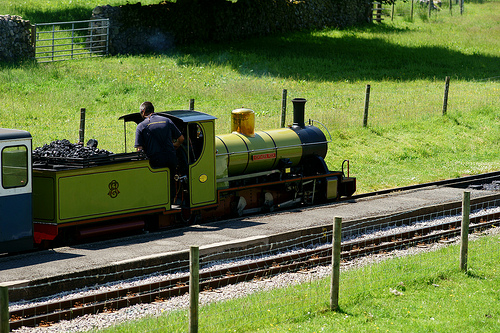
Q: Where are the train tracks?
A: On the gravel.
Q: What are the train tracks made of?
A: Metal.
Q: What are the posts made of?
A: Wood.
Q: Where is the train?
A: On the tracks.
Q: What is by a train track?
A: A field.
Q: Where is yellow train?
A: On tracks.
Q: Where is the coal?
A: Second compartment.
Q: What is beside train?
A: Tracks.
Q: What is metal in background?
A: A gate.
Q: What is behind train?
A: Grass field.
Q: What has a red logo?
A: Green train.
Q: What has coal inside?
A: Back of train.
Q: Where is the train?
A: On the track.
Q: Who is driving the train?
A: Man in the blue shirt.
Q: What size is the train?
A: Small.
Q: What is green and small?
A: The train.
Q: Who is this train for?
A: Kids.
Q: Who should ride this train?
A: Kids.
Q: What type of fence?
A: Wire.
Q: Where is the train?
A: Tracks.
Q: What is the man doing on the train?
A: Driving.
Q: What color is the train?
A: Yellow.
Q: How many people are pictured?
A: 1.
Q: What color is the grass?
A: Green.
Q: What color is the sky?
A: Blue.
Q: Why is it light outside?
A: Sunny.